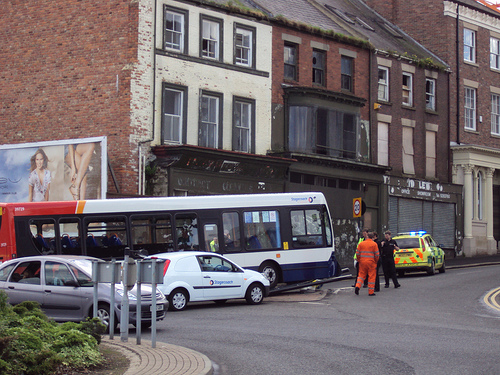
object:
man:
[350, 230, 378, 288]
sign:
[90, 259, 121, 286]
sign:
[120, 258, 138, 290]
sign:
[135, 255, 165, 285]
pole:
[90, 258, 99, 321]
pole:
[107, 256, 116, 338]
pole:
[118, 253, 129, 342]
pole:
[133, 259, 142, 345]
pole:
[149, 258, 158, 348]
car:
[390, 229, 447, 277]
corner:
[1, 272, 180, 375]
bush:
[1, 330, 64, 373]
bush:
[20, 311, 59, 334]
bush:
[53, 340, 105, 370]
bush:
[65, 318, 104, 358]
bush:
[10, 296, 38, 318]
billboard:
[0, 133, 109, 236]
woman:
[24, 148, 55, 204]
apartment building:
[1, 0, 499, 280]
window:
[159, 80, 184, 146]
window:
[198, 91, 220, 147]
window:
[232, 97, 253, 154]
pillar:
[459, 162, 476, 257]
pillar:
[485, 166, 497, 254]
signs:
[61, 256, 169, 340]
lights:
[407, 230, 429, 237]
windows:
[149, 1, 263, 73]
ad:
[0, 134, 108, 204]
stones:
[110, 333, 189, 373]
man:
[353, 231, 379, 297]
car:
[124, 240, 268, 308]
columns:
[460, 158, 496, 233]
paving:
[208, 302, 423, 359]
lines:
[482, 288, 500, 315]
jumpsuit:
[350, 240, 380, 296]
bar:
[375, 232, 439, 266]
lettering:
[212, 279, 233, 284]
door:
[195, 256, 243, 299]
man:
[376, 231, 402, 289]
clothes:
[353, 238, 379, 263]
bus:
[1, 191, 337, 285]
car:
[0, 255, 169, 330]